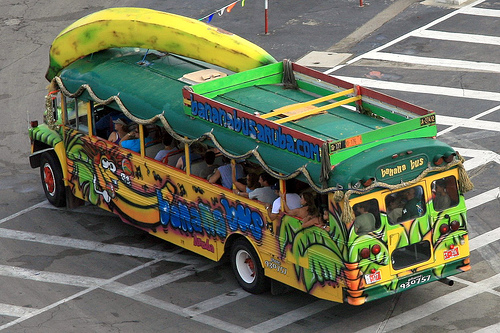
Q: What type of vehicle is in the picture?
A: A bus.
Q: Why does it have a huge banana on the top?
A: As an advertisement or tourist attraction.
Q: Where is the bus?
A: At an intersection.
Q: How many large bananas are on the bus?
A: One.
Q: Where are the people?
A: Riding in the bus.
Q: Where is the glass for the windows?
A: There is no glass.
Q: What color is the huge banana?
A: Yellow.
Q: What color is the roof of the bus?
A: Green.